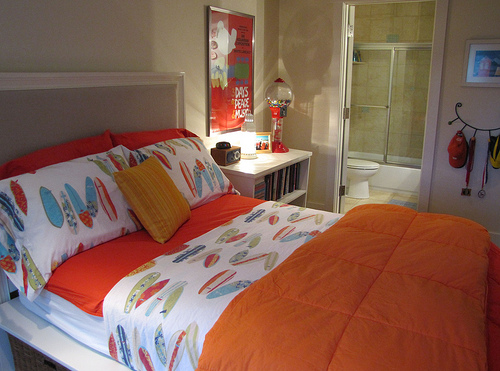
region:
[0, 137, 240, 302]
two pillows with surfboard patterned pillow cases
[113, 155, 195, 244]
a square yellow throw pillow on the bed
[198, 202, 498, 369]
orange comforter at bottom of bed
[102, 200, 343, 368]
surfboard patterned sheets on the bed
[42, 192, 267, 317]
orange sheet on the bed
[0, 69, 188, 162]
grey head board with white trim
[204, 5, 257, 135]
silver framed poster on the wall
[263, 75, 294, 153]
red gumball machine on white shelves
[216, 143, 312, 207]
white wooden book shelves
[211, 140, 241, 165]
a brown clock radio on top of white shelves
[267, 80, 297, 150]
red gumball machine on table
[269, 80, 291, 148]
gum ball machine on table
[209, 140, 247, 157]
time shown on electronic device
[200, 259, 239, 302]
red surf board on sheet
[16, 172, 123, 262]
pillow sheet with surfboards on it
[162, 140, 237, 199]
pillow sheet surfboard on it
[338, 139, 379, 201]
white porcelain toilet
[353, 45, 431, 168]
glass door to bath tub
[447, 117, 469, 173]
red hat hanging on the wall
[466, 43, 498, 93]
picture frame hanging on the wall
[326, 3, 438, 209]
open doorway of bathroom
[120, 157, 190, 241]
square yellow pillow on sheet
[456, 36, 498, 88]
picture in tan frame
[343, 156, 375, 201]
toilet with closed cover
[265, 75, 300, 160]
gumball machine on white surface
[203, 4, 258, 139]
poster in metal frame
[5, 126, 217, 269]
four pillows in cases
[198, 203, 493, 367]
folded orange comforter on bed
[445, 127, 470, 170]
red hat on hook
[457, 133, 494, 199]
two metals on ribbons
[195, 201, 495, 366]
orange comforter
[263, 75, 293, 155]
small gumball machine sitting on a bookshelf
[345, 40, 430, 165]
sliding glass shower door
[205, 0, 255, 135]
brightly-colored framed poster on a wall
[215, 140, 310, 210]
small white bookshelf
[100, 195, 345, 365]
white bedsheet with surfboards on it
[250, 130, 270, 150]
framed vacation picture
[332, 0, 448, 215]
white-framed bathroom door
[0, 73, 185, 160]
white and gray headboard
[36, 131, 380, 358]
the bed is made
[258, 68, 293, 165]
a candy dispenser on table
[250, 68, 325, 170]
a candy dispenser on table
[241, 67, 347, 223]
a candy dispenser on table